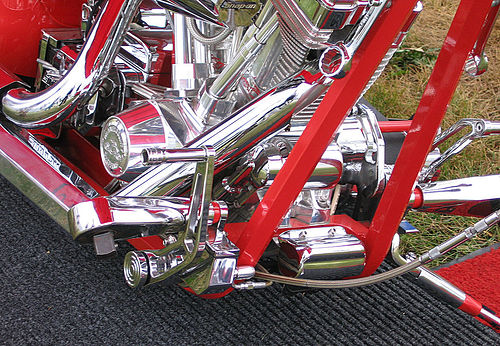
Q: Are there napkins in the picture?
A: No, there are no napkins.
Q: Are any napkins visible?
A: No, there are no napkins.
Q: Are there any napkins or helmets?
A: No, there are no napkins or helmets.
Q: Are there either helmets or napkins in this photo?
A: No, there are no napkins or helmets.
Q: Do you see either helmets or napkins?
A: No, there are no napkins or helmets.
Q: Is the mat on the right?
A: Yes, the mat is on the right of the image.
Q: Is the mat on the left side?
A: No, the mat is on the right of the image.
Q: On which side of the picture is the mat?
A: The mat is on the right of the image.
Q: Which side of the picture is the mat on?
A: The mat is on the right of the image.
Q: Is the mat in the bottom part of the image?
A: Yes, the mat is in the bottom of the image.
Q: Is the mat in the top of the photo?
A: No, the mat is in the bottom of the image.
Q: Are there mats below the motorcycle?
A: Yes, there is a mat below the motorcycle.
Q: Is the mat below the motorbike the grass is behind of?
A: Yes, the mat is below the motorbike.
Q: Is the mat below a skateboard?
A: No, the mat is below the motorbike.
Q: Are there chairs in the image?
A: No, there are no chairs.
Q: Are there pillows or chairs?
A: No, there are no chairs or pillows.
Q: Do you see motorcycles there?
A: Yes, there is a motorcycle.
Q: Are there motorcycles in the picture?
A: Yes, there is a motorcycle.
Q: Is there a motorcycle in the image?
A: Yes, there is a motorcycle.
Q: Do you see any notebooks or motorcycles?
A: Yes, there is a motorcycle.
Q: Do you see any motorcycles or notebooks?
A: Yes, there is a motorcycle.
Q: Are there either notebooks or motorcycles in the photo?
A: Yes, there is a motorcycle.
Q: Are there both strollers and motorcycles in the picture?
A: No, there is a motorcycle but no strollers.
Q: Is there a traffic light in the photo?
A: No, there are no traffic lights.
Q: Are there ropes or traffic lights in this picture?
A: No, there are no traffic lights or ropes.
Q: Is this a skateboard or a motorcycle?
A: This is a motorcycle.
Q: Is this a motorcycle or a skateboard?
A: This is a motorcycle.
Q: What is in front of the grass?
A: The motorcycle is in front of the grass.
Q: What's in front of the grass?
A: The motorcycle is in front of the grass.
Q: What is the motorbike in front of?
A: The motorbike is in front of the grass.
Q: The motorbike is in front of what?
A: The motorbike is in front of the grass.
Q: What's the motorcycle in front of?
A: The motorbike is in front of the grass.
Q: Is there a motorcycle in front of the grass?
A: Yes, there is a motorcycle in front of the grass.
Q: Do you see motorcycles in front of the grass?
A: Yes, there is a motorcycle in front of the grass.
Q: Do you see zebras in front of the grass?
A: No, there is a motorcycle in front of the grass.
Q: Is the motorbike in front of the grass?
A: Yes, the motorbike is in front of the grass.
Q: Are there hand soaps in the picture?
A: No, there are no hand soaps.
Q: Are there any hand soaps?
A: No, there are no hand soaps.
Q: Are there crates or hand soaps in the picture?
A: No, there are no hand soaps or crates.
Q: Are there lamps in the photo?
A: No, there are no lamps.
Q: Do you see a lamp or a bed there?
A: No, there are no lamps or beds.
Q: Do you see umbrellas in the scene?
A: No, there are no umbrellas.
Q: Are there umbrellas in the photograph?
A: No, there are no umbrellas.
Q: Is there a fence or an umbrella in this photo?
A: No, there are no umbrellas or fences.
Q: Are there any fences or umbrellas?
A: No, there are no umbrellas or fences.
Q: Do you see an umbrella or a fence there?
A: No, there are no umbrellas or fences.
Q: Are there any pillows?
A: No, there are no pillows.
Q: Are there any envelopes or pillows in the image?
A: No, there are no pillows or envelopes.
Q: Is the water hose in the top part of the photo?
A: Yes, the water hose is in the top of the image.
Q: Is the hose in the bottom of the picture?
A: No, the hose is in the top of the image.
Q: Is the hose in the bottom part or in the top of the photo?
A: The hose is in the top of the image.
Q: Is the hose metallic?
A: Yes, the hose is metallic.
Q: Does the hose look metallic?
A: Yes, the hose is metallic.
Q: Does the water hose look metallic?
A: Yes, the water hose is metallic.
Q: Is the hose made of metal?
A: Yes, the hose is made of metal.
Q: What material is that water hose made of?
A: The water hose is made of metal.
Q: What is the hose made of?
A: The water hose is made of metal.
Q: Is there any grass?
A: Yes, there is grass.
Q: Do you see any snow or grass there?
A: Yes, there is grass.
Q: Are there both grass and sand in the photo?
A: No, there is grass but no sand.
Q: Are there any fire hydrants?
A: No, there are no fire hydrants.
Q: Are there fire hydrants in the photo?
A: No, there are no fire hydrants.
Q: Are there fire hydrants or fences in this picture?
A: No, there are no fire hydrants or fences.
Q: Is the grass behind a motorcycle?
A: Yes, the grass is behind a motorcycle.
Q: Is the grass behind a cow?
A: No, the grass is behind a motorcycle.